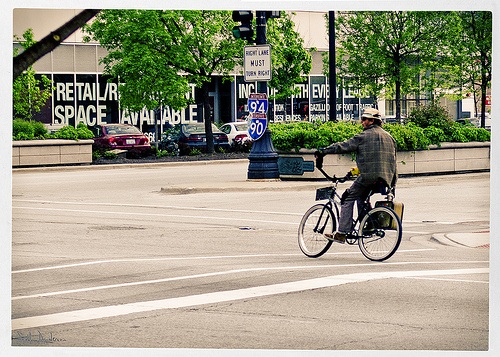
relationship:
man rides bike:
[307, 110, 401, 240] [299, 149, 403, 266]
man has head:
[307, 110, 401, 240] [355, 108, 380, 128]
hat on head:
[361, 106, 381, 120] [355, 108, 380, 128]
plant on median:
[275, 124, 320, 150] [264, 142, 492, 182]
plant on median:
[455, 122, 489, 145] [264, 142, 492, 182]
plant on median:
[419, 104, 451, 143] [264, 142, 492, 182]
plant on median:
[385, 121, 430, 148] [264, 142, 492, 182]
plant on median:
[331, 116, 363, 157] [264, 142, 492, 182]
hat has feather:
[361, 106, 381, 120] [373, 113, 380, 117]